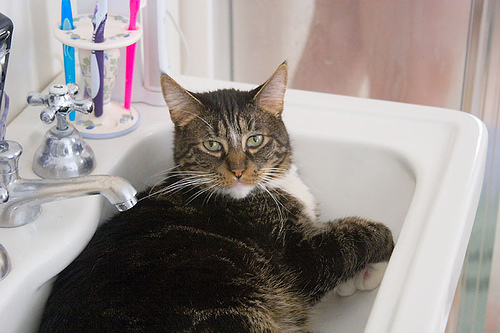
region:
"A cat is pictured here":
[155, 57, 365, 320]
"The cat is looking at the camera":
[154, 59, 332, 221]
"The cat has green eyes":
[154, 66, 308, 210]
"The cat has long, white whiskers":
[135, 63, 320, 247]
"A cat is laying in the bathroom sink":
[1, 52, 495, 331]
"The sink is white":
[0, 63, 498, 332]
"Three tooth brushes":
[41, 0, 146, 148]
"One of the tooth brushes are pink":
[41, 1, 160, 147]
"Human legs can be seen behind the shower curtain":
[236, 2, 496, 331]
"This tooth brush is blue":
[44, 0, 95, 135]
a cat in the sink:
[79, 76, 395, 329]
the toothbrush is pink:
[108, 2, 165, 137]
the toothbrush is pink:
[122, 3, 143, 128]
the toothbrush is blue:
[49, 2, 86, 94]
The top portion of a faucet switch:
[21, 76, 96, 126]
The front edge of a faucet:
[91, 171, 140, 216]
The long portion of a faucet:
[15, 174, 96, 209]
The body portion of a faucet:
[0, 139, 40, 229]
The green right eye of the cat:
[200, 137, 225, 154]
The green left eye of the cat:
[240, 125, 268, 155]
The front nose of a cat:
[222, 158, 252, 187]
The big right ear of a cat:
[155, 69, 205, 126]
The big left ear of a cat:
[246, 55, 308, 115]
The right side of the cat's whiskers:
[152, 168, 218, 205]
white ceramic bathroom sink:
[1, 58, 488, 331]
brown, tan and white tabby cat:
[36, 56, 394, 331]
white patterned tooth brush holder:
[53, 8, 141, 142]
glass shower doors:
[178, 0, 498, 330]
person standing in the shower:
[286, 0, 472, 110]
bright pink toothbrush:
[123, 0, 141, 111]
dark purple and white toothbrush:
[88, 0, 110, 119]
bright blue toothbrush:
[56, 0, 77, 123]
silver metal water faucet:
[0, 130, 140, 225]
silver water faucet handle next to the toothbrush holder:
[26, 82, 95, 181]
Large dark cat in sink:
[35, 48, 392, 330]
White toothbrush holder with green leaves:
[54, 0, 134, 142]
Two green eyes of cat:
[182, 131, 286, 156]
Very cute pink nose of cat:
[226, 163, 248, 179]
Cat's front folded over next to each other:
[314, 220, 396, 312]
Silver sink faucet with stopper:
[3, 133, 143, 223]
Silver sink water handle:
[17, 78, 97, 172]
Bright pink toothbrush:
[118, 0, 144, 121]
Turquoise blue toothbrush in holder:
[57, 0, 84, 123]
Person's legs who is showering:
[288, 0, 461, 108]